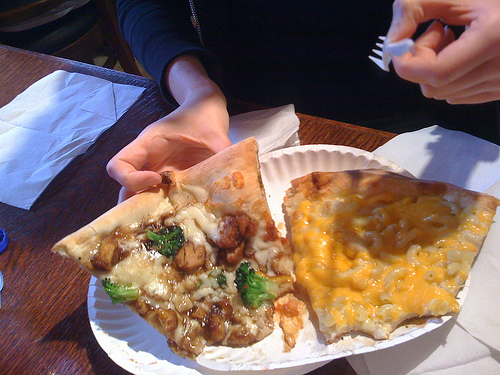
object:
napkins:
[379, 124, 500, 194]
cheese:
[402, 291, 430, 312]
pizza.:
[283, 160, 499, 339]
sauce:
[298, 251, 324, 269]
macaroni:
[282, 170, 500, 344]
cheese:
[351, 295, 378, 306]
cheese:
[303, 247, 325, 267]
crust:
[197, 137, 259, 201]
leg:
[91, 12, 146, 87]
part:
[0, 33, 110, 374]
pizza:
[48, 137, 300, 362]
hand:
[105, 99, 232, 214]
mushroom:
[169, 239, 211, 276]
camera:
[0, 0, 103, 42]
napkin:
[0, 70, 146, 208]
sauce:
[289, 192, 328, 223]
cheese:
[168, 203, 200, 226]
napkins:
[211, 101, 309, 152]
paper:
[273, 150, 309, 167]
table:
[0, 36, 495, 372]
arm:
[114, 1, 222, 93]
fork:
[365, 35, 417, 73]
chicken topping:
[90, 240, 123, 270]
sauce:
[360, 268, 372, 280]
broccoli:
[144, 225, 185, 257]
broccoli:
[233, 260, 280, 307]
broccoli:
[99, 276, 141, 305]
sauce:
[350, 271, 419, 329]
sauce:
[208, 314, 266, 342]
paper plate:
[193, 143, 469, 372]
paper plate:
[84, 260, 333, 373]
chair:
[0, 1, 143, 77]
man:
[96, 2, 499, 206]